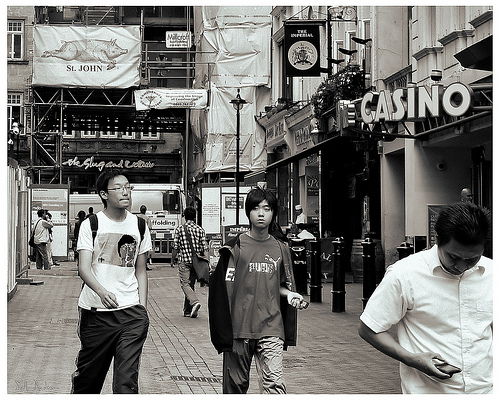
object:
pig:
[41, 38, 128, 66]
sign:
[32, 21, 142, 91]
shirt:
[76, 210, 150, 313]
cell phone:
[433, 361, 462, 377]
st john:
[66, 62, 104, 72]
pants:
[70, 305, 149, 394]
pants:
[220, 337, 288, 393]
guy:
[71, 168, 152, 394]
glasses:
[107, 183, 133, 192]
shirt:
[172, 220, 208, 266]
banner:
[30, 21, 143, 90]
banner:
[282, 18, 320, 78]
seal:
[286, 40, 318, 70]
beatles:
[125, 243, 134, 267]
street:
[10, 252, 400, 395]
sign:
[331, 79, 474, 133]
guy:
[357, 201, 497, 394]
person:
[29, 208, 53, 271]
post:
[308, 235, 322, 304]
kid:
[206, 187, 306, 391]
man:
[170, 205, 210, 321]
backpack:
[181, 224, 209, 285]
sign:
[60, 156, 156, 171]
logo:
[248, 254, 282, 273]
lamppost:
[233, 109, 244, 228]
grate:
[170, 372, 220, 386]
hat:
[295, 205, 302, 211]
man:
[206, 186, 309, 395]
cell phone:
[290, 295, 310, 311]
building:
[367, 0, 493, 280]